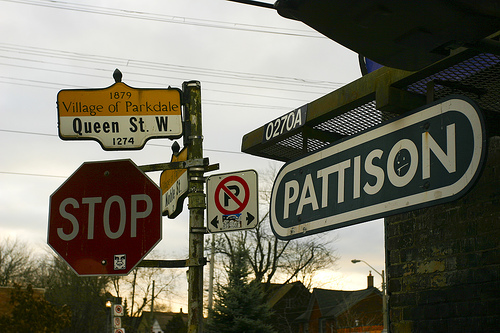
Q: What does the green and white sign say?
A: Pattison.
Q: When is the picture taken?
A: Sunset/sunrise.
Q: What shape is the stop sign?
A: Octagon.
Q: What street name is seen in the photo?
A: Queen St. W.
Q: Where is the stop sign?
A: Below the street name sign.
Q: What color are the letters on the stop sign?
A: White.